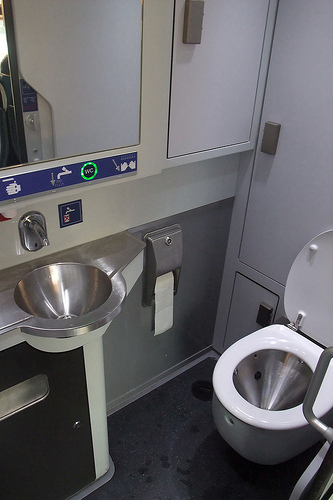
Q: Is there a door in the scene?
A: Yes, there is a door.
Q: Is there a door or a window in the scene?
A: Yes, there is a door.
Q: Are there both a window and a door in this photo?
A: No, there is a door but no windows.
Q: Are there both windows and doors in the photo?
A: No, there is a door but no windows.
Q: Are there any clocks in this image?
A: No, there are no clocks.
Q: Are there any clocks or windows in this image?
A: No, there are no clocks or windows.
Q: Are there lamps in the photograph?
A: No, there are no lamps.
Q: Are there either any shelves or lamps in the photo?
A: No, there are no lamps or shelves.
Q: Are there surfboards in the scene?
A: No, there are no surfboards.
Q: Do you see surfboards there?
A: No, there are no surfboards.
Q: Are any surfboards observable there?
A: No, there are no surfboards.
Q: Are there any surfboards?
A: No, there are no surfboards.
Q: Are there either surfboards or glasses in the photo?
A: No, there are no surfboards or glasses.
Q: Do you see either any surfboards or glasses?
A: No, there are no surfboards or glasses.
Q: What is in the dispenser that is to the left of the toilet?
A: The toilet paper is in the dispenser.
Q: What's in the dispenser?
A: The toilet paper is in the dispenser.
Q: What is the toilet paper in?
A: The toilet paper is in the dispenser.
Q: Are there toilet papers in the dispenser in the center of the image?
A: Yes, there is a toilet paper in the dispenser.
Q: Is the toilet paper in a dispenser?
A: Yes, the toilet paper is in a dispenser.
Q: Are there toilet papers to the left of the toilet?
A: Yes, there is a toilet paper to the left of the toilet.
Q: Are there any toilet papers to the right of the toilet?
A: No, the toilet paper is to the left of the toilet.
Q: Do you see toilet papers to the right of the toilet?
A: No, the toilet paper is to the left of the toilet.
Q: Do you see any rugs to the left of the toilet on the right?
A: No, there is a toilet paper to the left of the toilet.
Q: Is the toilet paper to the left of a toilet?
A: Yes, the toilet paper is to the left of a toilet.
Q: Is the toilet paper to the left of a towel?
A: No, the toilet paper is to the left of a toilet.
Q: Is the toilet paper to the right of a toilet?
A: No, the toilet paper is to the left of a toilet.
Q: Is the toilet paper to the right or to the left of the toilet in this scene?
A: The toilet paper is to the left of the toilet.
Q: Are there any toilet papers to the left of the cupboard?
A: Yes, there is a toilet paper to the left of the cupboard.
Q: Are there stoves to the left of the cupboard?
A: No, there is a toilet paper to the left of the cupboard.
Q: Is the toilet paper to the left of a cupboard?
A: Yes, the toilet paper is to the left of a cupboard.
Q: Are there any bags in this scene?
A: No, there are no bags.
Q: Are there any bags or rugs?
A: No, there are no bags or rugs.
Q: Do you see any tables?
A: No, there are no tables.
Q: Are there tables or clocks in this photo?
A: No, there are no tables or clocks.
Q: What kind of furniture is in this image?
A: The furniture is a cupboard.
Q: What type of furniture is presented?
A: The furniture is a cupboard.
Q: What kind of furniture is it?
A: The piece of furniture is a cupboard.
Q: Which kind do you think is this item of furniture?
A: This is a cupboard.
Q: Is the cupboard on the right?
A: Yes, the cupboard is on the right of the image.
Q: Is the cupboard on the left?
A: No, the cupboard is on the right of the image.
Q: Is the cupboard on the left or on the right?
A: The cupboard is on the right of the image.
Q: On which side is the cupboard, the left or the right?
A: The cupboard is on the right of the image.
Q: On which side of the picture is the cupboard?
A: The cupboard is on the right of the image.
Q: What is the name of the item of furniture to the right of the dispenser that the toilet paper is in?
A: The piece of furniture is a cupboard.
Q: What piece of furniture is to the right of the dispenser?
A: The piece of furniture is a cupboard.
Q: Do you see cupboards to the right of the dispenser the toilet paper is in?
A: Yes, there is a cupboard to the right of the dispenser.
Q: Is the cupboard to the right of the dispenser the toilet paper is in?
A: Yes, the cupboard is to the right of the dispenser.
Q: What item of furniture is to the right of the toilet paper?
A: The piece of furniture is a cupboard.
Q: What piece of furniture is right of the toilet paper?
A: The piece of furniture is a cupboard.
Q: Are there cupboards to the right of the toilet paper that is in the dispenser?
A: Yes, there is a cupboard to the right of the toilet paper.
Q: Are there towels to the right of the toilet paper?
A: No, there is a cupboard to the right of the toilet paper.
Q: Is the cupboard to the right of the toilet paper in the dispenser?
A: Yes, the cupboard is to the right of the toilet paper.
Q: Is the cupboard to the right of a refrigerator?
A: No, the cupboard is to the right of the toilet paper.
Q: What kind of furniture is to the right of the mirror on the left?
A: The piece of furniture is a cupboard.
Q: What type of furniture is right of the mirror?
A: The piece of furniture is a cupboard.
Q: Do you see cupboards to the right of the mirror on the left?
A: Yes, there is a cupboard to the right of the mirror.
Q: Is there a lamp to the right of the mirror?
A: No, there is a cupboard to the right of the mirror.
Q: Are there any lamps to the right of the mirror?
A: No, there is a cupboard to the right of the mirror.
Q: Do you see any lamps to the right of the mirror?
A: No, there is a cupboard to the right of the mirror.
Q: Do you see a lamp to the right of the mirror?
A: No, there is a cupboard to the right of the mirror.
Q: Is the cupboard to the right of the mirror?
A: Yes, the cupboard is to the right of the mirror.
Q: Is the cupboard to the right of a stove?
A: No, the cupboard is to the right of the mirror.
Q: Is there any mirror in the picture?
A: Yes, there is a mirror.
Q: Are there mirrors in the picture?
A: Yes, there is a mirror.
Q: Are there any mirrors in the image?
A: Yes, there is a mirror.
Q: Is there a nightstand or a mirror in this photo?
A: Yes, there is a mirror.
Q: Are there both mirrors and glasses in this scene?
A: No, there is a mirror but no glasses.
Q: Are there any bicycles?
A: No, there are no bicycles.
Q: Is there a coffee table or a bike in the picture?
A: No, there are no bikes or coffee tables.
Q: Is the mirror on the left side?
A: Yes, the mirror is on the left of the image.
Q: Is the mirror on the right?
A: No, the mirror is on the left of the image.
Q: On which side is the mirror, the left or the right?
A: The mirror is on the left of the image.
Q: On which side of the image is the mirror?
A: The mirror is on the left of the image.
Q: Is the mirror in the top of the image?
A: Yes, the mirror is in the top of the image.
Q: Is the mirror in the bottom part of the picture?
A: No, the mirror is in the top of the image.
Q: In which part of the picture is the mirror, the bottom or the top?
A: The mirror is in the top of the image.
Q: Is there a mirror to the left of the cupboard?
A: Yes, there is a mirror to the left of the cupboard.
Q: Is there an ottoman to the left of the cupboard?
A: No, there is a mirror to the left of the cupboard.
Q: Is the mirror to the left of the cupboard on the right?
A: Yes, the mirror is to the left of the cupboard.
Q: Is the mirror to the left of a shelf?
A: No, the mirror is to the left of the cupboard.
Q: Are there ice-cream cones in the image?
A: No, there are no ice-cream cones.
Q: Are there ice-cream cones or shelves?
A: No, there are no ice-cream cones or shelves.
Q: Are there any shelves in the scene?
A: No, there are no shelves.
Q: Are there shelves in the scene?
A: No, there are no shelves.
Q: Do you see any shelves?
A: No, there are no shelves.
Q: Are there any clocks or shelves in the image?
A: No, there are no shelves or clocks.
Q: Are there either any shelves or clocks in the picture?
A: No, there are no shelves or clocks.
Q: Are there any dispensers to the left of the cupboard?
A: Yes, there is a dispenser to the left of the cupboard.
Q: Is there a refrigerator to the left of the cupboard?
A: No, there is a dispenser to the left of the cupboard.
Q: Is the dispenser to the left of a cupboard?
A: Yes, the dispenser is to the left of a cupboard.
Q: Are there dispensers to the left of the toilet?
A: Yes, there is a dispenser to the left of the toilet.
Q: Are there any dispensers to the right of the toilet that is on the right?
A: No, the dispenser is to the left of the toilet.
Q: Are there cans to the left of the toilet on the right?
A: No, there is a dispenser to the left of the toilet.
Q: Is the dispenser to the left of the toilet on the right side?
A: Yes, the dispenser is to the left of the toilet.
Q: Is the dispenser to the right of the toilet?
A: No, the dispenser is to the left of the toilet.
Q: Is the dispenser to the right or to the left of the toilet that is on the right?
A: The dispenser is to the left of the toilet.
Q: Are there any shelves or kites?
A: No, there are no shelves or kites.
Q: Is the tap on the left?
A: Yes, the tap is on the left of the image.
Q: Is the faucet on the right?
A: No, the faucet is on the left of the image.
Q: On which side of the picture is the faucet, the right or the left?
A: The faucet is on the left of the image.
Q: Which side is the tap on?
A: The tap is on the left of the image.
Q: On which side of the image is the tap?
A: The tap is on the left of the image.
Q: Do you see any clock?
A: No, there are no clocks.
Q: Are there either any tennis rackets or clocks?
A: No, there are no clocks or tennis rackets.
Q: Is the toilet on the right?
A: Yes, the toilet is on the right of the image.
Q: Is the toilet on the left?
A: No, the toilet is on the right of the image.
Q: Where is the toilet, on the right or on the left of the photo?
A: The toilet is on the right of the image.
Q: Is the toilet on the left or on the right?
A: The toilet is on the right of the image.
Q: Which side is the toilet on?
A: The toilet is on the right of the image.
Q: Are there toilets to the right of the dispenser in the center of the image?
A: Yes, there is a toilet to the right of the dispenser.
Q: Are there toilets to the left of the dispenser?
A: No, the toilet is to the right of the dispenser.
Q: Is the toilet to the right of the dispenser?
A: Yes, the toilet is to the right of the dispenser.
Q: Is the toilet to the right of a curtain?
A: No, the toilet is to the right of the dispenser.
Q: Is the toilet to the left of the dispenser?
A: No, the toilet is to the right of the dispenser.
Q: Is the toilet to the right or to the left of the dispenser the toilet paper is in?
A: The toilet is to the right of the dispenser.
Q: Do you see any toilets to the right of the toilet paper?
A: Yes, there is a toilet to the right of the toilet paper.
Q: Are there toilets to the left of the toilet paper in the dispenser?
A: No, the toilet is to the right of the toilet paper.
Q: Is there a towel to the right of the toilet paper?
A: No, there is a toilet to the right of the toilet paper.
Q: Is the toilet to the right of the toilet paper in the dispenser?
A: Yes, the toilet is to the right of the toilet paper.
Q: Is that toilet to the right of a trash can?
A: No, the toilet is to the right of the toilet paper.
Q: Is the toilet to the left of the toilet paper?
A: No, the toilet is to the right of the toilet paper.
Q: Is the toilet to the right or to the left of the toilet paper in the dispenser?
A: The toilet is to the right of the toilet paper.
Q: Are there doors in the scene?
A: Yes, there is a door.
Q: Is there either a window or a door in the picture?
A: Yes, there is a door.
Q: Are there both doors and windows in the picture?
A: No, there is a door but no windows.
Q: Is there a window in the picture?
A: No, there are no windows.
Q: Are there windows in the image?
A: No, there are no windows.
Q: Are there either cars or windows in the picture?
A: No, there are no windows or cars.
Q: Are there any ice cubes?
A: No, there are no ice cubes.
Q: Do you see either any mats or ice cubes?
A: No, there are no ice cubes or mats.